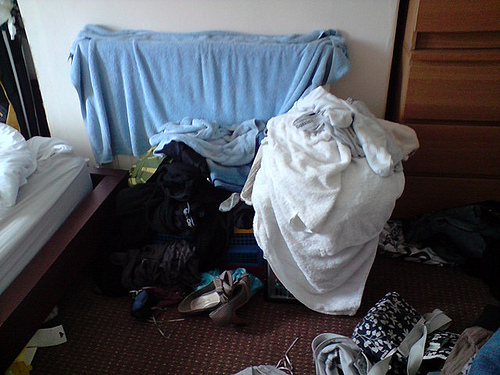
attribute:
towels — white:
[248, 85, 420, 252]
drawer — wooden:
[405, 6, 499, 57]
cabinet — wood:
[402, 1, 498, 212]